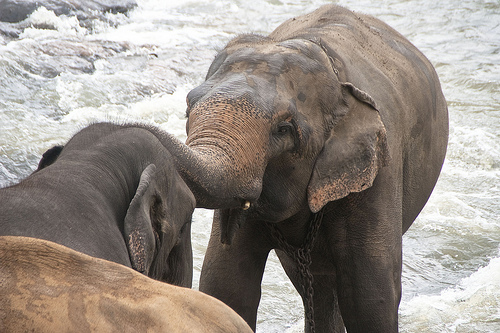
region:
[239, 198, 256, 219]
edge of a tusk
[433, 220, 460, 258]
part of a ground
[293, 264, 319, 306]
part of a chain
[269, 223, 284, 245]
edge of a chain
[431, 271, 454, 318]
part of a water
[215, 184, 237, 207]
part of a trunk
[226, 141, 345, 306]
the elephant is wearing a chain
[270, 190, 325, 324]
the elephant is wearing a chain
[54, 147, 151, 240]
the elephant is gray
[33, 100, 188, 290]
the elephant is gray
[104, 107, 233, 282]
the elephant is gray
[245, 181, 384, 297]
the elephant is gray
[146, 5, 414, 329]
Elephants in the water.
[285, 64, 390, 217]
Ears on the elephant.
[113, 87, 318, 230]
Trunk on the elephant.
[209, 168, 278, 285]
Tusk on the elephant.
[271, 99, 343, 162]
Eye on the elephant.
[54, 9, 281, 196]
Water in the background.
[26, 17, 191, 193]
Waves in the water.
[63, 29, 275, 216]
White caps on the waves.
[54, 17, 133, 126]
Froth in the water.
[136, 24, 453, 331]
Gray elephant in the water.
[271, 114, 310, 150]
EYE OF LEFT ELEPHANT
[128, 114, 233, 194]
Trunk of Elephant on left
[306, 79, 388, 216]
Ear of elephant on left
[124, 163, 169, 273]
Ear of elephant on left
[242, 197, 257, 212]
Tusk of elephant on right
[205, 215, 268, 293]
Part of leg of left elephant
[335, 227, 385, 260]
Part of leg of elephant on the left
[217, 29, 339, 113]
Part of head of elephant on left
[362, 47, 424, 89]
Part of back of elephant on left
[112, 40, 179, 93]
Part of ground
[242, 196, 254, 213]
Small tusk protruding from an elephant's face.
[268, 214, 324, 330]
Heavy chains hanging from the neck of an elephant.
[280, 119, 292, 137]
Weary looking eye of a brown elephant.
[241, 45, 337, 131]
Water spots located on top of elephant's head.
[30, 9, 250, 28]
Swirling and splashing water swirling about.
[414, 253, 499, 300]
Visible waves boucing on top of the water.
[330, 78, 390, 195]
Torn hole in elephant's leftside ear.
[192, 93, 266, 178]
Discolored nose and trunk of an elephant.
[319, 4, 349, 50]
Pointed hump in the back of a brown colored elephant.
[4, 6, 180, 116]
Large water waves breaking against the shore and rocks.